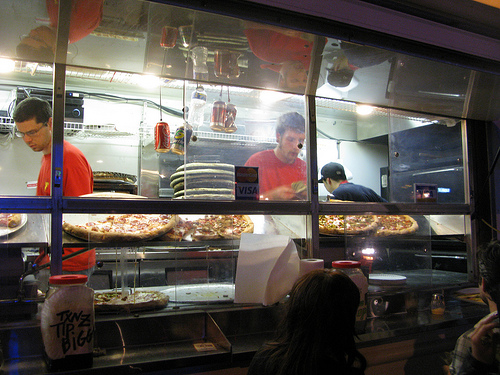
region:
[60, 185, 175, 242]
a whole pizza on shelf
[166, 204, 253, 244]
a whole pizza on shelf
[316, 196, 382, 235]
a whole pizza on shelf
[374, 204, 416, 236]
a whole pizza on shelf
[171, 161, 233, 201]
a stack of plates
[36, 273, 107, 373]
a large tip jar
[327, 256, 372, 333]
a large tip jar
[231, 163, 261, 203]
credit card acceptance logo stickers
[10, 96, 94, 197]
a chef behind the counter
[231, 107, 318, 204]
a chef behind the counter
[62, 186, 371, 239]
pizzas being sold by slice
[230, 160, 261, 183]
mastercard accepted sign in window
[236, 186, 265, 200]
visa accepted sign in window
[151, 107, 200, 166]
soda for sale in window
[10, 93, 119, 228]
man in red shirt working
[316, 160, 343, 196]
man wearing black baseball hat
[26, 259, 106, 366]
tip jar on ledge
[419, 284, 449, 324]
parmesan cheese topping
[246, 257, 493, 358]
people waiting to buy pizza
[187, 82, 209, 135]
water bottles for sale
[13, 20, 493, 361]
these guys are busy making pizzas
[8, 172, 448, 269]
a variety of pizzas in the counter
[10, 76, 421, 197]
three workers at the restaurant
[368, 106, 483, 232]
a pizza oven for cooking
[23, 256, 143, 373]
a tip jar for money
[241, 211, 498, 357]
the head of two customers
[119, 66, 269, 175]
pop hanging up for display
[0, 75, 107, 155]
a radio on the wall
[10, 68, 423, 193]
steel appliances in the kitchen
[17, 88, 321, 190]
these workers look incredibly busy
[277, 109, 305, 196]
Person has brown hair.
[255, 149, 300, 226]
Person is wearing red shirt.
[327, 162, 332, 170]
Person wearing black hat.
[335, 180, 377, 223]
Person wearing black shirt.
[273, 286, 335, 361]
Person has black hair.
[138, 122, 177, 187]
Can of coca cola hanging near window.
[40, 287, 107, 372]
Black writing on paper plate.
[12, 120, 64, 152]
Glasses on person's face.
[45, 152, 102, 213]
Person wearing red shirt.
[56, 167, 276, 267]
Pizzas in window front.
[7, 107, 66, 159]
man is wearing glasses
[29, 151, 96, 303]
man wearing red shirt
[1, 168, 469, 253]
pizzas in display window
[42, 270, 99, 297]
jar has red top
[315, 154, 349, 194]
person wearing black hat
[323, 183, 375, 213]
person wearing black shirt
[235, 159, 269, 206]
sign on display window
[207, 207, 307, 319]
paper bag on counter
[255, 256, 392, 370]
woman's hair is brown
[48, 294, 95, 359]
black lettering on jar